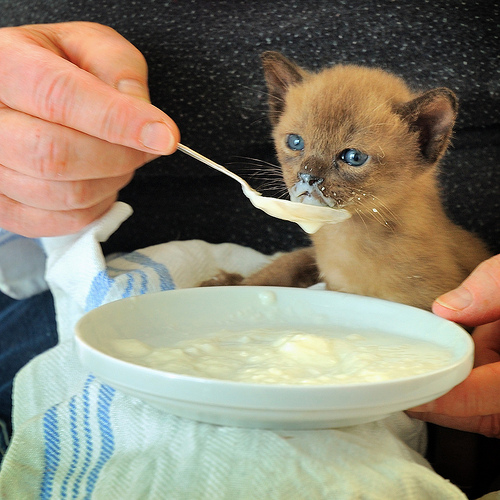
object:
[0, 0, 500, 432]
person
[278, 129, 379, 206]
face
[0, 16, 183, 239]
hand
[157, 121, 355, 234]
spoon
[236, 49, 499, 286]
kitten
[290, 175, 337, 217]
fed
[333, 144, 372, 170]
eyes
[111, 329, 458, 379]
food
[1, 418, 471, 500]
towel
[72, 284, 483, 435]
bowl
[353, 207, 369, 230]
whiskers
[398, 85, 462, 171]
ear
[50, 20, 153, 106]
thumb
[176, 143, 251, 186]
handle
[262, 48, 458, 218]
head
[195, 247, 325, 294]
arm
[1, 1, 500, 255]
shirt